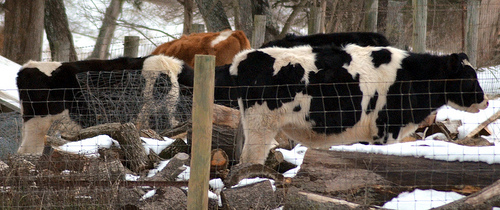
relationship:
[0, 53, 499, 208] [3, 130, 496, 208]
snow covering ground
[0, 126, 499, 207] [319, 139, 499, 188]
snow on log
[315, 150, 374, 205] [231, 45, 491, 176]
terrain under cow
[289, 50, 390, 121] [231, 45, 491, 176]
spots on cow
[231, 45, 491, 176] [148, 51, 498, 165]
cow in closure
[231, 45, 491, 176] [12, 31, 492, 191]
cow in group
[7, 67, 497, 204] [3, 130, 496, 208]
fence on ground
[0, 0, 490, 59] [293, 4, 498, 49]
trees on back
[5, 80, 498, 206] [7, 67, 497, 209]
chicken wire on fence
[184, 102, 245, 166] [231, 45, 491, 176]
log behind cow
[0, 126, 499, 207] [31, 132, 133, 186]
snow on tree stump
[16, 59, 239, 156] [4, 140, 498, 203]
cow on field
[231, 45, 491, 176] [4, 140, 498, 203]
cow on field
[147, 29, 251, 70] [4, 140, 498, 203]
cows on field